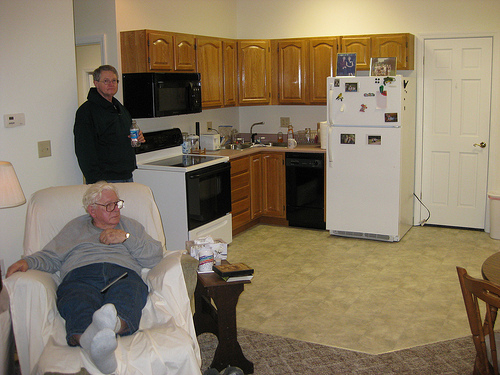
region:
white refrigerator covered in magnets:
[322, 71, 417, 245]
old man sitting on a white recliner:
[21, 186, 174, 368]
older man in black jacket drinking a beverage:
[71, 60, 147, 183]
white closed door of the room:
[418, 32, 488, 232]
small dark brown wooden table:
[190, 272, 264, 374]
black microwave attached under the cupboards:
[121, 73, 203, 120]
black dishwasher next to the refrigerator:
[284, 151, 322, 227]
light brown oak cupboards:
[192, 33, 329, 110]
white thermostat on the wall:
[1, 110, 28, 127]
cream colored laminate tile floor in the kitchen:
[266, 243, 428, 350]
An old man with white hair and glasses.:
[6, 180, 163, 374]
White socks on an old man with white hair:
[78, 302, 123, 374]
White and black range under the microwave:
[127, 128, 234, 253]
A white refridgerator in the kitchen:
[323, 73, 417, 241]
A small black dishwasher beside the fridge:
[283, 151, 326, 228]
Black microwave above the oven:
[121, 70, 204, 118]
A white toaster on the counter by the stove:
[198, 130, 222, 151]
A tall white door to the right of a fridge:
[421, 34, 494, 231]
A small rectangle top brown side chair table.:
[181, 240, 254, 374]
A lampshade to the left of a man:
[1, 160, 26, 211]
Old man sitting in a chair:
[6, 185, 202, 373]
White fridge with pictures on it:
[321, 70, 418, 245]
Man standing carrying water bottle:
[68, 63, 145, 183]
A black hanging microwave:
[121, 68, 203, 121]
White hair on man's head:
[81, 180, 123, 223]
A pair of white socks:
[76, 299, 129, 373]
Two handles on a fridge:
[321, 82, 339, 169]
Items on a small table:
[189, 234, 255, 372]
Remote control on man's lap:
[93, 259, 144, 300]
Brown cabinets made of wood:
[118, 29, 416, 107]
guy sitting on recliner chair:
[19, 165, 181, 373]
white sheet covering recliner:
[19, 173, 184, 368]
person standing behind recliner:
[47, 46, 168, 223]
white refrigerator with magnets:
[315, 51, 431, 251]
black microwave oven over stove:
[120, 55, 230, 170]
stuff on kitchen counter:
[179, 119, 353, 236]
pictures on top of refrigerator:
[306, 42, 421, 148]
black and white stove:
[134, 127, 259, 258]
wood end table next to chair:
[78, 228, 283, 372]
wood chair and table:
[407, 242, 499, 373]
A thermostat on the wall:
[4, 113, 27, 128]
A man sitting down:
[5, 181, 165, 373]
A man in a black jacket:
[70, 63, 144, 185]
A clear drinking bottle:
[126, 117, 140, 148]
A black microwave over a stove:
[124, 73, 203, 118]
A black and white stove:
[131, 127, 233, 254]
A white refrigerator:
[323, 76, 413, 241]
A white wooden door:
[421, 38, 493, 228]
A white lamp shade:
[0, 160, 26, 208]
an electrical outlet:
[205, 120, 215, 133]